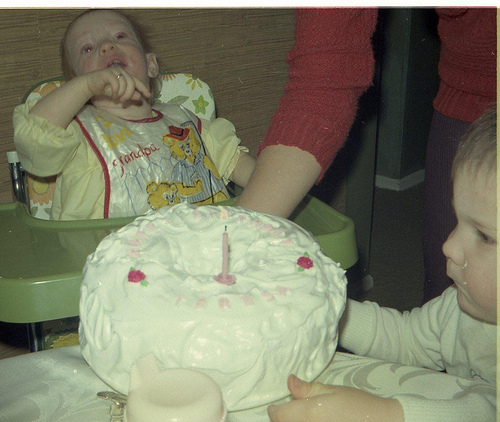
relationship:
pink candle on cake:
[217, 225, 235, 285] [86, 200, 363, 392]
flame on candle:
[213, 203, 233, 223] [218, 232, 234, 280]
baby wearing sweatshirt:
[10, 8, 258, 259] [332, 278, 484, 408]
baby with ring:
[11, 8, 258, 216] [115, 68, 125, 80]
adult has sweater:
[206, 7, 498, 332] [250, 8, 485, 188]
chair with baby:
[0, 178, 363, 358] [14, 9, 271, 206]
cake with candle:
[75, 199, 351, 416] [220, 224, 231, 281]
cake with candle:
[75, 199, 351, 416] [210, 221, 238, 288]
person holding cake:
[232, 5, 498, 308] [88, 213, 351, 413]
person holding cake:
[232, 5, 497, 290] [75, 199, 351, 416]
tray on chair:
[9, 168, 375, 355] [7, 83, 351, 348]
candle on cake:
[216, 222, 240, 293] [61, 185, 398, 380]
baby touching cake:
[267, 103, 499, 420] [75, 199, 351, 416]